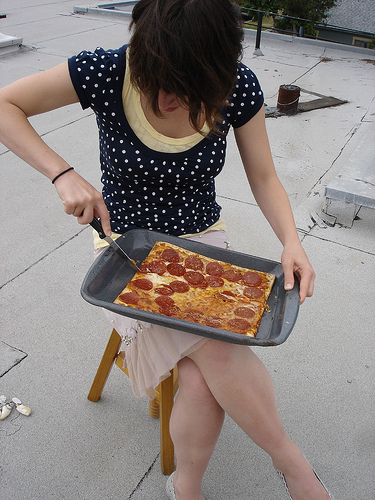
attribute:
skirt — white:
[133, 341, 170, 380]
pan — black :
[80, 228, 299, 345]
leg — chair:
[63, 312, 127, 408]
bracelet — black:
[49, 165, 74, 183]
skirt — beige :
[127, 330, 181, 376]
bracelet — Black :
[41, 161, 94, 187]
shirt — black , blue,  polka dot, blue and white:
[62, 43, 265, 235]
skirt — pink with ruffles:
[76, 237, 305, 402]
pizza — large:
[112, 238, 277, 340]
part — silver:
[104, 233, 139, 269]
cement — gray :
[309, 331, 360, 413]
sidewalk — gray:
[293, 136, 356, 181]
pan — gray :
[90, 217, 321, 353]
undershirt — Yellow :
[82, 55, 234, 244]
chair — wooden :
[87, 322, 177, 474]